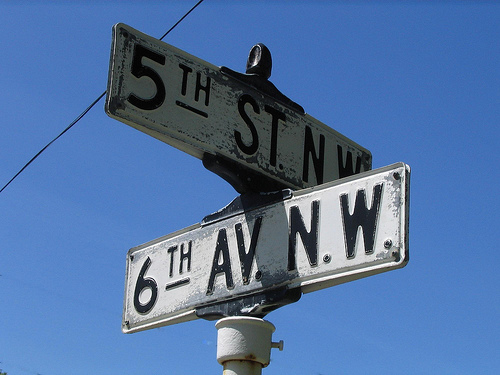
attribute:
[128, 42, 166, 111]
number — black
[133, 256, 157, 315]
number — black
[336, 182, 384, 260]
letter — black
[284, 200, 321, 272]
letter — black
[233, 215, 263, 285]
letter — black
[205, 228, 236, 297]
letter — black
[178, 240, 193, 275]
letter — black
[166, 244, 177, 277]
letter — black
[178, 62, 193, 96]
letter — black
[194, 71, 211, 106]
letter — black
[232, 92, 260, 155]
letter — black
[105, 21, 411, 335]
signs — black, white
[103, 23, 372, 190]
background — white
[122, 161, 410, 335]
background — white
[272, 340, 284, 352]
screw — white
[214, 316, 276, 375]
pole — white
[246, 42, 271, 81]
screw — black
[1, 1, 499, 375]
sky — blue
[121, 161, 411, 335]
sign — black, white, gray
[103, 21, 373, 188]
sign — black, white, gray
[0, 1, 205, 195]
wire — black